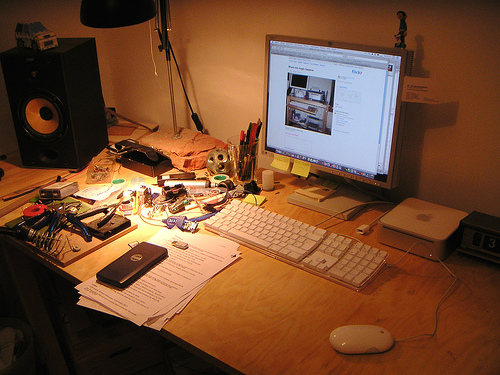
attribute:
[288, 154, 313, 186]
post-it note — yellow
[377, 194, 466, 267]
computer — white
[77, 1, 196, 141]
lamp — adjustable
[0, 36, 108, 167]
speaker — black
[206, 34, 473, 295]
computer — mini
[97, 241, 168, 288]
phone — black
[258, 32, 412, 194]
screen — lit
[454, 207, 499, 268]
clock — black, digital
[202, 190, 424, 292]
keyboard — white, silver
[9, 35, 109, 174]
speaker — black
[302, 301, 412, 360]
mouse — white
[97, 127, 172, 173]
stapler — gray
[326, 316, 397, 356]
mouse — white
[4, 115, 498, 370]
desk — wooden